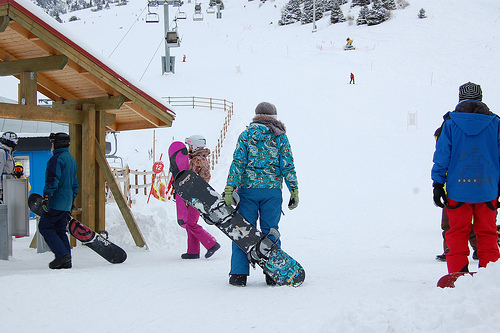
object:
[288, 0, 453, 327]
slope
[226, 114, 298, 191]
parka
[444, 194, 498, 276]
pants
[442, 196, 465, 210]
suspenders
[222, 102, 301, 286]
person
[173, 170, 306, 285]
snowboard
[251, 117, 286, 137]
hood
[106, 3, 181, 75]
chairlift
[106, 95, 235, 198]
fencing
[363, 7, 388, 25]
pine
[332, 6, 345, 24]
pine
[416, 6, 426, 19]
pine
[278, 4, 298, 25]
pine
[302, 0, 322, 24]
pine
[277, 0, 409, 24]
cluster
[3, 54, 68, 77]
beam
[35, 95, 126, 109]
beam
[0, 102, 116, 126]
beam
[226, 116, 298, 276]
outfit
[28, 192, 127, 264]
snowboard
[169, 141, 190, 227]
snowboard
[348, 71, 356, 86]
man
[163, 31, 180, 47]
seat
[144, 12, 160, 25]
seat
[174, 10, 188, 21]
seat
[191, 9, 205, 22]
seat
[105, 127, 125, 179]
seat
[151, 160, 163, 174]
sign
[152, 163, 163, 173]
number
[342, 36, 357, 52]
man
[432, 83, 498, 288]
man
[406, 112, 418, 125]
marker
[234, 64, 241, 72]
marker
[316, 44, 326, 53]
marker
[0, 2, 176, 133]
roof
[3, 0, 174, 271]
break area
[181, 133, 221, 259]
woman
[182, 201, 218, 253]
pants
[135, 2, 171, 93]
wire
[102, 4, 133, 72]
wire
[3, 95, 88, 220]
building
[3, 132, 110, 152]
roof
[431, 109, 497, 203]
jacket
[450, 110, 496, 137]
hood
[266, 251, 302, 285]
design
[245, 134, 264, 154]
design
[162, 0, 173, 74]
pole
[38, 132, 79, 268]
person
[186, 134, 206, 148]
helmet